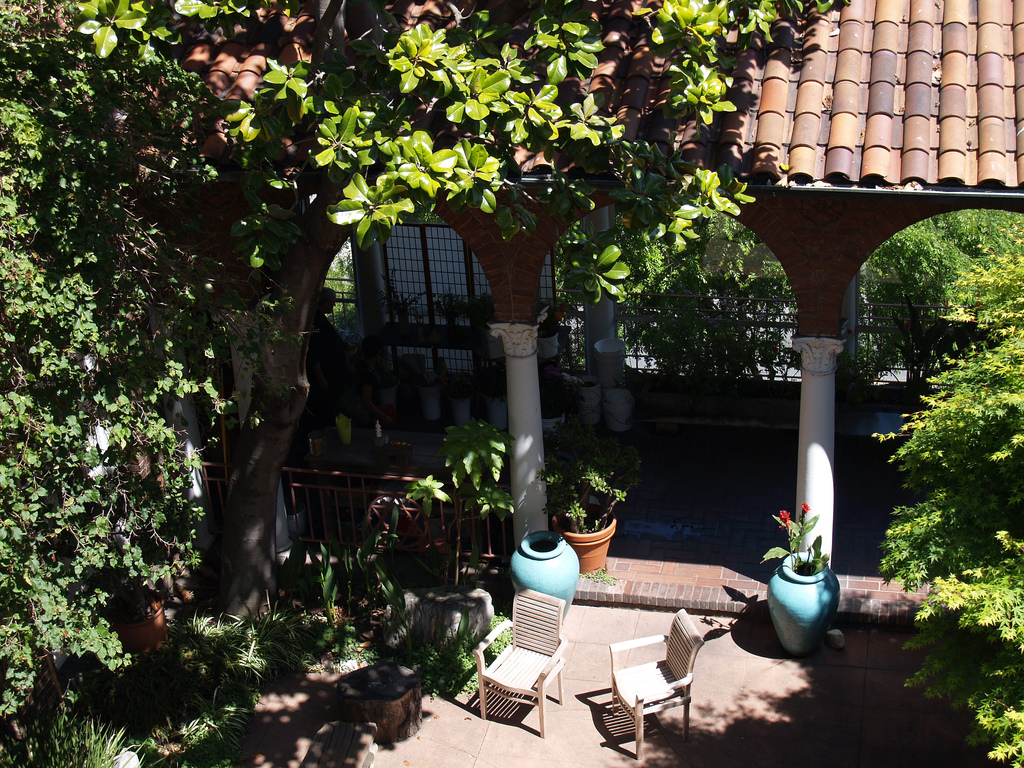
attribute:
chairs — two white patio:
[464, 593, 726, 745]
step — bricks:
[602, 580, 691, 619]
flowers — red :
[760, 500, 845, 583]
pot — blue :
[760, 547, 847, 643]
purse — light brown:
[585, 405, 637, 451]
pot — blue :
[773, 560, 841, 641]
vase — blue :
[773, 551, 845, 638]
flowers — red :
[760, 495, 821, 575]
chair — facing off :
[460, 584, 733, 749]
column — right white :
[499, 301, 847, 567]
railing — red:
[285, 453, 493, 579]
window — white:
[360, 207, 520, 415]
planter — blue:
[767, 568, 854, 709]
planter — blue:
[491, 479, 584, 560]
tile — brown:
[815, 67, 882, 132]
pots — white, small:
[387, 384, 513, 432]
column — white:
[780, 324, 852, 579]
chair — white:
[594, 585, 718, 765]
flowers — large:
[776, 520, 818, 575]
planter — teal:
[776, 567, 833, 630]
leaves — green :
[294, 90, 500, 238]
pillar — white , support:
[489, 313, 554, 540]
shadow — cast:
[463, 704, 535, 726]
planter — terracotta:
[560, 531, 628, 571]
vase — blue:
[763, 551, 841, 657]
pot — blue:
[765, 549, 843, 656]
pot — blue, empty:
[510, 521, 575, 625]